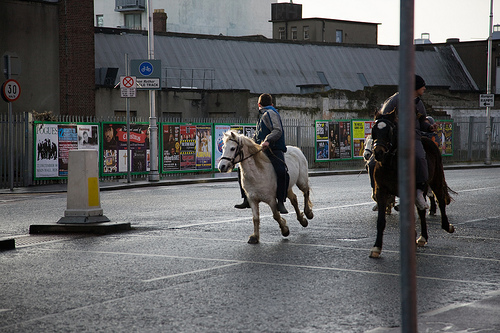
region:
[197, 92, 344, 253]
man on a horse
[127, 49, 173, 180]
street sign on a pole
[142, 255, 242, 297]
white line painted on road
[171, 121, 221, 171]
signs on a fence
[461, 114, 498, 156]
fence on side of road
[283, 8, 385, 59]
top of a building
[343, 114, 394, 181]
head of a horse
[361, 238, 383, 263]
hoof of a horse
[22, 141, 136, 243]
statue in median of road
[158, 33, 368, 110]
awning of a building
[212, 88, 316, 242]
person on the horse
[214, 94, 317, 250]
person on the white horse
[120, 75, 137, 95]
sign on the pole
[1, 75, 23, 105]
sign attached to pole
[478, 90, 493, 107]
sign on the pole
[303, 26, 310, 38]
window on the building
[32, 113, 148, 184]
gate behind pole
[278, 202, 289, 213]
boot on the man's foot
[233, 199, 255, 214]
boot on the man's foot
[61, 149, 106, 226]
concrete pole on the concrete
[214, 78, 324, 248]
A person riding on a horse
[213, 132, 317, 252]
A white horse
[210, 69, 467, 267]
Two people riding horses on the road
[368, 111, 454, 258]
A black horse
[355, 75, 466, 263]
A man on a black horse.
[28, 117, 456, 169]
Signs on a fence.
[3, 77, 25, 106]
A round speed limit sign.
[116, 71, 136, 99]
A white and red traffic sign.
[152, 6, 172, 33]
The chimney on a building.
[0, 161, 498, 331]
The road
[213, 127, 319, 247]
A horse is white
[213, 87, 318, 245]
Person sitting on a horse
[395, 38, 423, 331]
A gray colored pole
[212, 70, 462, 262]
Two people are riding horses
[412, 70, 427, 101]
Black hat on a guy's head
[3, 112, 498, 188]
A long fence with signs on it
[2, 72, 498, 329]
Two horses are walking on the road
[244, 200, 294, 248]
Two legs of a horse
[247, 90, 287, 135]
A guy is looking behind him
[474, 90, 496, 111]
Black arrow on white sign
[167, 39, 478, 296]
people riding horses in street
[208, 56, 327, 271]
the horse is white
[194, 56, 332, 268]
the horse is galloping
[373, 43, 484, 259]
the horse is brown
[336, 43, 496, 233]
the boy is looking back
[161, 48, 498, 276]
two horses and two riders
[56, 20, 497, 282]
they are riding in a city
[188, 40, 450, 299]
boys are riding horses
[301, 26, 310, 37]
building has a window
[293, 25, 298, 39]
building has a window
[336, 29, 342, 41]
building has a window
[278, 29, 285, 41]
building has a window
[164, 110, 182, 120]
building has a window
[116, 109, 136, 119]
building has a window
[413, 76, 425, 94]
person has a head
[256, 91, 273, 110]
person has a head